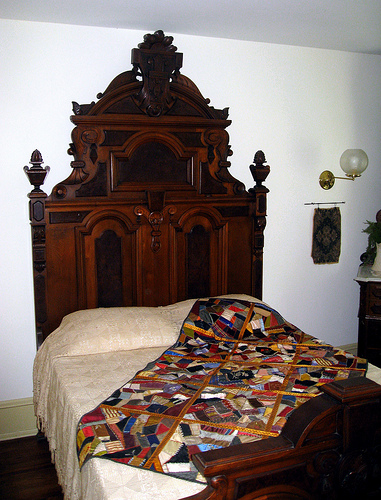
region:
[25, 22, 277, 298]
tall ornamental wood headboard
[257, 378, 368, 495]
wood footboard on bed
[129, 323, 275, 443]
colorful quilt on bed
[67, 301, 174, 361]
pillow under white bedspread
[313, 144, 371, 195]
wall lamp with brass base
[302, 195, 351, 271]
materinal hanging from rod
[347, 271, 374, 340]
table with white top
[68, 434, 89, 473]
corner of quilt on side of bed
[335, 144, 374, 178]
round white glass on lamp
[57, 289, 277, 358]
two pillows at head of bed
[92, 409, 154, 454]
quilt square on bedspread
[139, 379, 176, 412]
quilt square on bedspread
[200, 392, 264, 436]
quilt square on bedspread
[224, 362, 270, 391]
quilt square on bedspread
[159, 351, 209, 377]
quilt square on bedspread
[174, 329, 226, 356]
quilt square on bedspread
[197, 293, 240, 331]
quilt square on bedspread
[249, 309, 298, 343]
quilt square on bedspread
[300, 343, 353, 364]
quilt square on bedspread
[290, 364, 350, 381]
quilt square on bedspread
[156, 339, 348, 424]
the comforter is colored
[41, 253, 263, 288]
the headboard is wooden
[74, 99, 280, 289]
the headdboard is black and brown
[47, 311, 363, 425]
the bed is well spread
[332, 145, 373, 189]
the bulb is circular in shape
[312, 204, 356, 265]
the carpet is dark grey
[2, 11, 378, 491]
the room is a bedroom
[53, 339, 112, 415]
the bedshhet is silver in color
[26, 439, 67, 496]
the floor is wooden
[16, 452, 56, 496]
the floor is brown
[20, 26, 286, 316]
An ornate headboard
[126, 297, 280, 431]
A colorful quilt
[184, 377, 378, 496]
A wooden footboard on a bed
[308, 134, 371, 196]
A wall lamp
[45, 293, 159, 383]
A white comforter on a bed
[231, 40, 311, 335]
A white bedroom wall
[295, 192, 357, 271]
A small tapestry wall hanging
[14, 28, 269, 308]
A large wooden headboard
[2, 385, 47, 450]
A beige baseboard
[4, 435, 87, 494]
A bed on a wooden floor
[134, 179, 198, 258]
Large wood headboard on bed.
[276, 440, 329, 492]
Large wood foot board on bed.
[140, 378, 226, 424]
Multi colored quilt laying on bed.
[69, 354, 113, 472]
White bed spread on bed.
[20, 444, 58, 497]
Dark hard wood floors in room.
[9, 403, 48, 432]
Cream base boards on wall.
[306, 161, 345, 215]
Gold light fixture on wall.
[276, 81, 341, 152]
Wall is painted white in room.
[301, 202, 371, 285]
Wall hanging attached to wall.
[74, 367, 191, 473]
Bed is made in room.